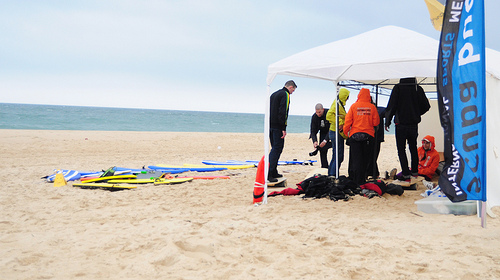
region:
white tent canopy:
[271, 24, 438, 84]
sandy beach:
[16, 210, 351, 274]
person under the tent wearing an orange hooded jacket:
[343, 85, 378, 143]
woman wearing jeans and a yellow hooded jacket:
[327, 85, 349, 173]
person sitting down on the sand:
[412, 135, 443, 184]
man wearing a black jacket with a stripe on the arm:
[269, 78, 294, 183]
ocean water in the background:
[0, 115, 264, 130]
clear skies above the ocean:
[16, 8, 258, 85]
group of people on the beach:
[271, 71, 437, 181]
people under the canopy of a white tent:
[333, 74, 436, 204]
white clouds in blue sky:
[13, 7, 81, 94]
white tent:
[291, 21, 415, 81]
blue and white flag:
[447, 7, 492, 175]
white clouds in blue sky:
[14, 24, 48, 66]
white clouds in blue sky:
[143, 27, 181, 89]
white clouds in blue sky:
[77, 23, 114, 75]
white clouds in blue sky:
[149, 16, 190, 76]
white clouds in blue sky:
[219, 10, 253, 90]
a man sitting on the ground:
[413, 132, 438, 177]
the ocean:
[8, 101, 255, 144]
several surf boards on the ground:
[41, 155, 246, 192]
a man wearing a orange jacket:
[416, 132, 433, 172]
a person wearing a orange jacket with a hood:
[347, 84, 374, 136]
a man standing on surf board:
[263, 82, 293, 192]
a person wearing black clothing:
[383, 69, 425, 181]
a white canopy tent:
[271, 27, 429, 112]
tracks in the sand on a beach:
[12, 232, 378, 279]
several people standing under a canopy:
[286, 38, 440, 215]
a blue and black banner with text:
[434, 0, 487, 200]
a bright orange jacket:
[343, 88, 377, 134]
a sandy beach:
[3, 202, 497, 276]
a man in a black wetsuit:
[263, 80, 295, 182]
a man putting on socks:
[308, 102, 330, 171]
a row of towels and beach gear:
[45, 151, 322, 199]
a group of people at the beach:
[272, 77, 439, 184]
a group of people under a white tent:
[258, 24, 499, 204]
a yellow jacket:
[329, 88, 350, 133]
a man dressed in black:
[394, 75, 423, 180]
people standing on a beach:
[268, 78, 431, 184]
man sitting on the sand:
[419, 134, 439, 180]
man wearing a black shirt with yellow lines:
[268, 86, 290, 130]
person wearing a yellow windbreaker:
[325, 89, 350, 136]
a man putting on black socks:
[309, 137, 328, 159]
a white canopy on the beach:
[263, 22, 443, 209]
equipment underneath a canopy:
[265, 168, 425, 198]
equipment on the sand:
[43, 157, 315, 190]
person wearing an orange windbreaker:
[342, 86, 380, 138]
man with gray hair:
[313, 103, 324, 118]